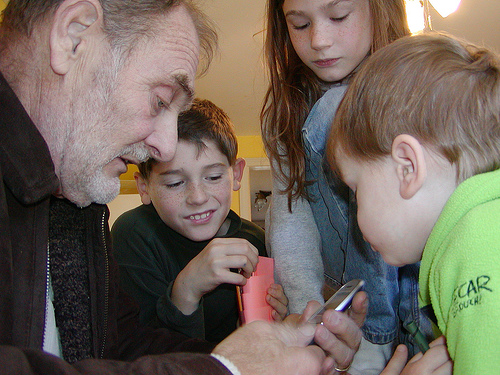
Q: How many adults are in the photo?
A: One.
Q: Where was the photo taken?
A: In a house.